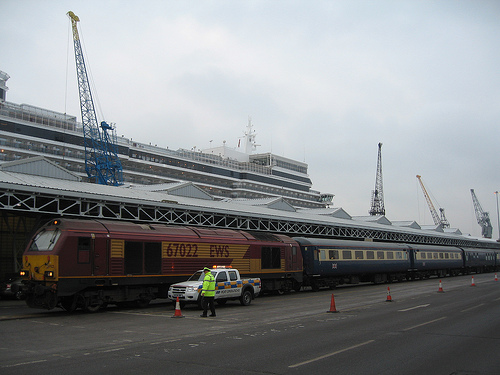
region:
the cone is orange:
[327, 292, 338, 317]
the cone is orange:
[327, 294, 335, 309]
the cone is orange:
[330, 295, 342, 315]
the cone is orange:
[323, 288, 334, 316]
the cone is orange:
[331, 291, 348, 324]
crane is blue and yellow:
[59, 15, 147, 206]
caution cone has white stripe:
[166, 298, 197, 326]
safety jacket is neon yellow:
[190, 270, 227, 316]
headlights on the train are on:
[15, 254, 63, 284]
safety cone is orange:
[314, 288, 363, 342]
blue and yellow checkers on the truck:
[213, 278, 282, 299]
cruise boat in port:
[4, 116, 341, 222]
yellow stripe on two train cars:
[293, 230, 480, 277]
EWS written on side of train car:
[208, 245, 240, 259]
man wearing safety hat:
[200, 256, 215, 273]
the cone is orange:
[383, 285, 395, 303]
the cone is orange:
[379, 282, 389, 302]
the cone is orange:
[387, 285, 394, 300]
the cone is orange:
[386, 288, 388, 304]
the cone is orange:
[385, 288, 392, 308]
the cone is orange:
[384, 283, 389, 305]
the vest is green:
[204, 278, 206, 293]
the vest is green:
[209, 280, 218, 291]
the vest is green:
[203, 278, 216, 300]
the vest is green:
[204, 276, 214, 291]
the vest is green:
[206, 283, 220, 292]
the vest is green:
[205, 283, 213, 294]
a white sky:
[1, 0, 496, 241]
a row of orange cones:
[321, 262, 496, 327]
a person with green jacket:
[195, 260, 220, 317]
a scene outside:
[2, 10, 482, 370]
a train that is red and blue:
[15, 195, 496, 305]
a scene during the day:
[6, 7, 496, 372]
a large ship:
[0, 67, 331, 214]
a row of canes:
[312, 116, 499, 251]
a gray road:
[1, 263, 496, 373]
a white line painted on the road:
[280, 332, 377, 373]